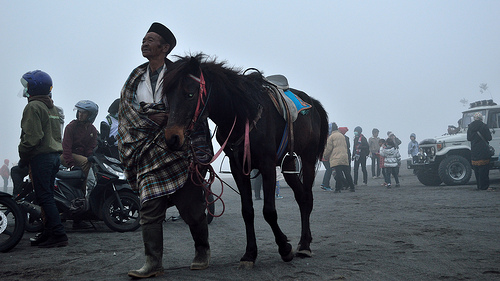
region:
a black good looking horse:
[155, 49, 330, 269]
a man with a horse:
[121, 15, 333, 276]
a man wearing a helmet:
[13, 67, 70, 249]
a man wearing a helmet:
[63, 99, 97, 169]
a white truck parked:
[413, 92, 498, 183]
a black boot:
[128, 222, 160, 277]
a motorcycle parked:
[30, 124, 143, 226]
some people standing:
[319, 115, 417, 187]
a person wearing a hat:
[466, 110, 493, 187]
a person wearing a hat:
[113, 17, 215, 279]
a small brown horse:
[157, 50, 331, 266]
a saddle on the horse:
[249, 67, 309, 175]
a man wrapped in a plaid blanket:
[115, 18, 215, 277]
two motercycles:
[2, 152, 140, 253]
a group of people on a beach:
[317, 121, 404, 191]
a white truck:
[407, 98, 498, 188]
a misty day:
[1, 3, 496, 188]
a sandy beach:
[1, 156, 498, 279]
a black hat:
[139, 21, 176, 49]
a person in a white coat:
[320, 122, 353, 189]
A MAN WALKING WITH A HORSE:
[100, 13, 346, 279]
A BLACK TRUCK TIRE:
[436, 149, 480, 191]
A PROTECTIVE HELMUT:
[67, 92, 106, 128]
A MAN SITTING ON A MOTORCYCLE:
[51, 93, 153, 238]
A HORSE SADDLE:
[236, 63, 301, 95]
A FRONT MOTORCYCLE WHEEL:
[98, 185, 160, 237]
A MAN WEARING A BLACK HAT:
[130, 13, 185, 81]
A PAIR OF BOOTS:
[112, 217, 219, 279]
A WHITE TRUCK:
[407, 93, 497, 188]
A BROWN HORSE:
[159, 50, 338, 275]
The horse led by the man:
[159, 45, 336, 273]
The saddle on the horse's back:
[243, 72, 310, 121]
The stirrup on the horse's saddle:
[276, 148, 306, 182]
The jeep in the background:
[400, 81, 498, 182]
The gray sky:
[2, 0, 497, 165]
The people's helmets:
[11, 68, 103, 125]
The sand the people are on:
[1, 164, 498, 279]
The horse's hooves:
[228, 239, 323, 274]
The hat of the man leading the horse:
[147, 21, 177, 51]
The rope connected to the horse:
[176, 136, 232, 224]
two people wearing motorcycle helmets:
[19, 59, 104, 190]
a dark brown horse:
[161, 55, 339, 267]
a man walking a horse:
[100, 17, 332, 279]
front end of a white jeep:
[403, 96, 498, 187]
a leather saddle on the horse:
[245, 62, 313, 180]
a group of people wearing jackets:
[326, 119, 407, 191]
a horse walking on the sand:
[154, 49, 342, 277]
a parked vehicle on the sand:
[396, 95, 496, 189]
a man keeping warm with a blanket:
[116, 14, 219, 270]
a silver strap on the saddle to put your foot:
[281, 145, 301, 178]